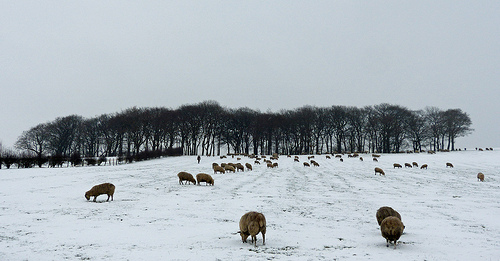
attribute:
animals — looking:
[177, 156, 253, 188]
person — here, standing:
[196, 155, 201, 165]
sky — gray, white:
[1, 1, 498, 148]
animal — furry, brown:
[84, 182, 114, 203]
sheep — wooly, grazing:
[195, 173, 214, 185]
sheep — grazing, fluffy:
[178, 171, 196, 184]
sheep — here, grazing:
[375, 168, 385, 175]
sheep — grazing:
[475, 173, 483, 181]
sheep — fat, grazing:
[381, 216, 405, 247]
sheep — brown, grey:
[377, 206, 402, 224]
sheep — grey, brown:
[303, 163, 309, 167]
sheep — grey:
[446, 162, 454, 167]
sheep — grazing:
[420, 164, 428, 170]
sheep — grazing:
[326, 156, 332, 161]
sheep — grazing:
[393, 163, 403, 169]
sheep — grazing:
[403, 163, 411, 169]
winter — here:
[1, 3, 498, 257]